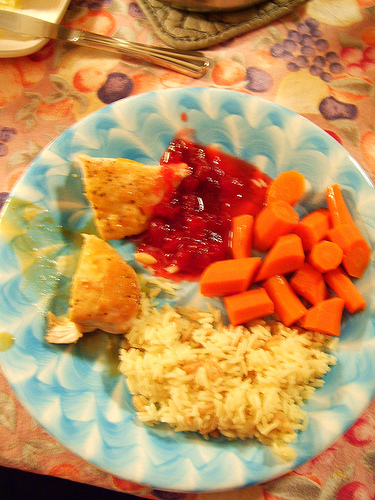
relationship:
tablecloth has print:
[1, 1, 373, 498] [4, 3, 375, 192]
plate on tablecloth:
[0, 86, 374, 490] [1, 1, 373, 498]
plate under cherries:
[0, 86, 374, 490] [132, 136, 273, 285]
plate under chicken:
[0, 86, 374, 490] [48, 155, 190, 345]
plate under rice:
[0, 86, 374, 490] [116, 294, 340, 465]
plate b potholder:
[0, 86, 374, 490] [132, 0, 306, 52]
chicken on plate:
[48, 155, 190, 345] [0, 86, 374, 490]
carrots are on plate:
[200, 171, 371, 338] [0, 86, 374, 490]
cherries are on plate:
[132, 136, 273, 285] [0, 86, 374, 490]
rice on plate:
[116, 294, 340, 465] [0, 86, 374, 490]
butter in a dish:
[1, 0, 30, 18] [2, 0, 76, 63]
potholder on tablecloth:
[132, 0, 306, 52] [1, 1, 373, 498]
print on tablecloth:
[4, 3, 375, 192] [1, 1, 373, 498]